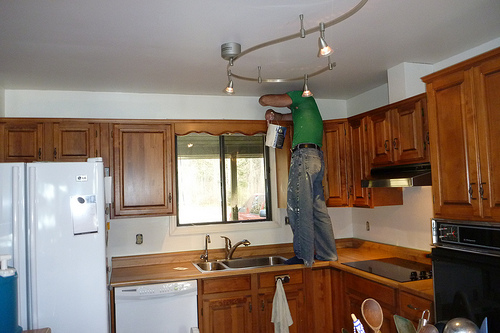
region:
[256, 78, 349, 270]
a man standing on a kitchen counter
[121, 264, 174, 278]
brown wood surface of the kitchen counter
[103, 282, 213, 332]
white door of the dishwasher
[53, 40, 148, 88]
white ceiling of the kitchen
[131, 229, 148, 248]
bare electrical outlet on the wall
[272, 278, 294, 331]
white towel hanging from the cabinet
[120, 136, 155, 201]
brown wood surface of the cabinet door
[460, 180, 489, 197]
black metal knobs of the cabinet doors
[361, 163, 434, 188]
grey metal hood over the stove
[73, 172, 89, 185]
grey logo on the white refridgerator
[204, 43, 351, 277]
the man installs lights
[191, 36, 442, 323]
the man has a green shirt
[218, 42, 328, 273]
the man wears jeans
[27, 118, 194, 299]
white appliances in kitchen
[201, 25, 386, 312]
the man stands on counter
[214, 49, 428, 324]
the man is working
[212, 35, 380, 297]
home repairman is working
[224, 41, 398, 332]
he is working on lights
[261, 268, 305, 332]
the dish towel is white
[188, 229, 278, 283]
the sink is stainless steel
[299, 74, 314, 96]
Metal light with tiny globe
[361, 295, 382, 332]
Spoon used for cooking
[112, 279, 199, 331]
A white dishwasher installed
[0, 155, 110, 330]
A big white refrigerator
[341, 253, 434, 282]
Stovetop on a counter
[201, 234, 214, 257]
A spray hose for a sink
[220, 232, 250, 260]
A faucet on a sink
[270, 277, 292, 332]
A type of rag on a handle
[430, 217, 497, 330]
A stove installed into the wall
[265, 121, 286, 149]
Paint can being held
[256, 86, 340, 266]
Man holding paint can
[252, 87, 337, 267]
Man in green shirt and jeans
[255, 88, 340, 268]
Man in green shirt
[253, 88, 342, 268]
Man standing on counter top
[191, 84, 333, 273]
Man standing by sink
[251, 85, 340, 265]
Man painting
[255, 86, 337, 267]
Man touching ceiling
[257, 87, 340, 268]
Man crouching under ceiling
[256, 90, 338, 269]
Man wearing belt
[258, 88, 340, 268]
Man holding can with white paint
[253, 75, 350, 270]
man standing on the counter top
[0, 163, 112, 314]
white fridge in the kitchen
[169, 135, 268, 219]
window over the kitchen sink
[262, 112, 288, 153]
can of white paint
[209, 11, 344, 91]
curved lighting fixture in the kitchen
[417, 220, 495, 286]
black oven in the kitchen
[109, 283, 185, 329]
dishwasher under the counter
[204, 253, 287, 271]
double stainless steel sink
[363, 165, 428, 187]
hood over the stove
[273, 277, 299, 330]
towel hanging on the cabinet